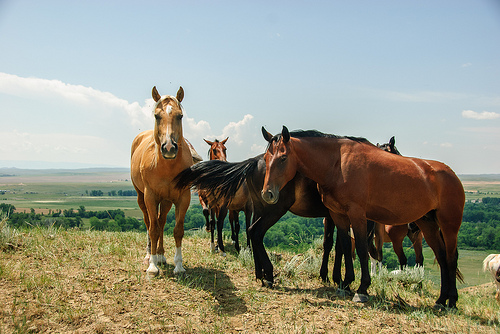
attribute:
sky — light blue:
[206, 20, 418, 68]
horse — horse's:
[326, 130, 431, 199]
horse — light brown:
[132, 80, 193, 277]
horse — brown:
[256, 122, 464, 307]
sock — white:
[169, 247, 185, 273]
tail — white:
[483, 247, 493, 271]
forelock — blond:
[156, 94, 179, 109]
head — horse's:
[144, 85, 194, 160]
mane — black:
[291, 129, 371, 149]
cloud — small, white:
[458, 105, 498, 122]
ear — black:
[279, 126, 294, 145]